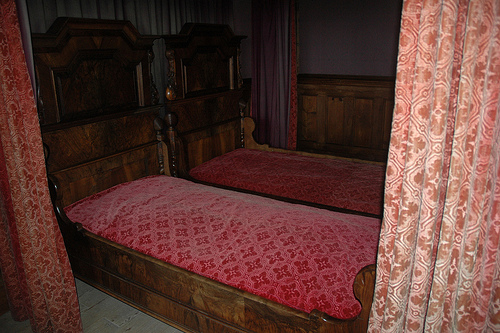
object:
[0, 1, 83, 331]
fabric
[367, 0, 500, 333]
fabric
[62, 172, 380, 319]
fabric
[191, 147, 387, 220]
fabric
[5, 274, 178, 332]
floor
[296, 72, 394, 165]
cupboard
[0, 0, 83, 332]
curtain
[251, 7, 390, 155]
wall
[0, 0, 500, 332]
room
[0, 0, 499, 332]
scene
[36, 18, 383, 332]
bed frame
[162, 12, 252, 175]
headboard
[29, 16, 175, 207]
headboard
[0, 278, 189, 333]
ground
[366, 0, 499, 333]
curtain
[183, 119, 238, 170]
wood paneling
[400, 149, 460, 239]
design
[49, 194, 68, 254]
edge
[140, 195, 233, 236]
top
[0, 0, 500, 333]
bed